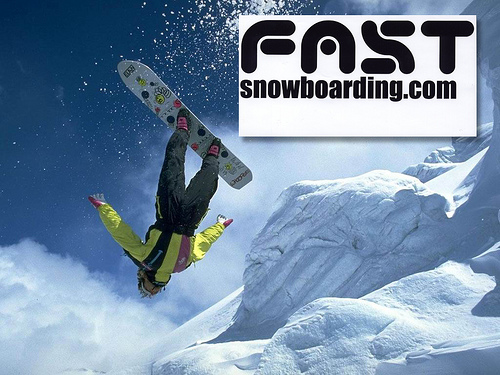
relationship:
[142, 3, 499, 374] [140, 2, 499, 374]
mountains covered in snow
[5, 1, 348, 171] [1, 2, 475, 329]
snow in air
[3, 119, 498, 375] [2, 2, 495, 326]
clouds in sky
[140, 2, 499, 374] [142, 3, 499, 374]
snow on mountains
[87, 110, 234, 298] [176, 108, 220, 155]
snowboarder wearing boots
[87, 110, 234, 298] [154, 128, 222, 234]
snowboarder wearing pants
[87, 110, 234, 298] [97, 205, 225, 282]
snowboarder wearing coat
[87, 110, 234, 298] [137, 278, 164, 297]
snowboarder wearing goggles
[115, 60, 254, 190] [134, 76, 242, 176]
snowboard has stickers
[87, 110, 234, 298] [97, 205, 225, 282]
snowboarder has coat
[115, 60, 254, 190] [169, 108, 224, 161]
snowboard on feet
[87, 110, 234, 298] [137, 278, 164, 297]
snowboarder has goggles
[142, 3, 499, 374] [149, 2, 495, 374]
mountains has ice